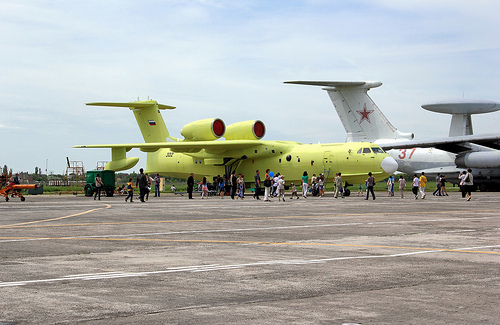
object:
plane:
[70, 99, 398, 197]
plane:
[283, 80, 499, 193]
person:
[459, 169, 474, 202]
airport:
[0, 168, 499, 320]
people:
[93, 173, 105, 201]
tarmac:
[0, 192, 499, 324]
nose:
[379, 156, 398, 175]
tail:
[85, 100, 177, 144]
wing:
[69, 140, 293, 173]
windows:
[285, 154, 293, 163]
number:
[398, 147, 407, 160]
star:
[355, 102, 374, 126]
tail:
[282, 80, 415, 144]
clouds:
[53, 9, 207, 54]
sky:
[1, 0, 499, 79]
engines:
[180, 117, 227, 141]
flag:
[147, 120, 157, 126]